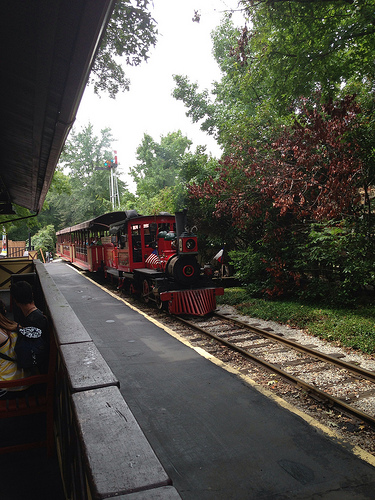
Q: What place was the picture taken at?
A: It was taken at the pavement.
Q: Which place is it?
A: It is a pavement.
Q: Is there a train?
A: Yes, there is a train.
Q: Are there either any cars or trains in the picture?
A: Yes, there is a train.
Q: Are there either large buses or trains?
A: Yes, there is a large train.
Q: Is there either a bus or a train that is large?
A: Yes, the train is large.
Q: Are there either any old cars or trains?
A: Yes, there is an old train.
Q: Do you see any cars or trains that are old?
A: Yes, the train is old.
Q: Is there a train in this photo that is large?
A: Yes, there is a train that is large.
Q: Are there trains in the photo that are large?
A: Yes, there is a train that is large.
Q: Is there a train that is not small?
A: Yes, there is a large train.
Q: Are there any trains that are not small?
A: Yes, there is a large train.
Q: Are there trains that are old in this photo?
A: Yes, there is an old train.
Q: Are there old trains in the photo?
A: Yes, there is an old train.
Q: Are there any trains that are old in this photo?
A: Yes, there is an old train.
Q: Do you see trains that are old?
A: Yes, there is a train that is old.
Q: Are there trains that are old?
A: Yes, there is a train that is old.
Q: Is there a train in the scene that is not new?
A: Yes, there is a old train.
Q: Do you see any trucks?
A: No, there are no trucks.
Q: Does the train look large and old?
A: Yes, the train is large and old.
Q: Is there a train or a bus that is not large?
A: No, there is a train but it is large.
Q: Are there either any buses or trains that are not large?
A: No, there is a train but it is large.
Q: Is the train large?
A: Yes, the train is large.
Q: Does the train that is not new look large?
A: Yes, the train is large.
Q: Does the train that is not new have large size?
A: Yes, the train is large.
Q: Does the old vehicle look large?
A: Yes, the train is large.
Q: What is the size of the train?
A: The train is large.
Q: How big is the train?
A: The train is large.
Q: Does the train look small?
A: No, the train is large.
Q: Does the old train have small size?
A: No, the train is large.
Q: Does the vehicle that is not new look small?
A: No, the train is large.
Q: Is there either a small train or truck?
A: No, there is a train but it is large.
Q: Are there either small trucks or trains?
A: No, there is a train but it is large.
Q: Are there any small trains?
A: No, there is a train but it is large.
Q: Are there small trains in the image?
A: No, there is a train but it is large.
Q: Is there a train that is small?
A: No, there is a train but it is large.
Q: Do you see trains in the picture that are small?
A: No, there is a train but it is large.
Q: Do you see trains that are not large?
A: No, there is a train but it is large.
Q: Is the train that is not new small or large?
A: The train is large.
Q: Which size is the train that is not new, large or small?
A: The train is large.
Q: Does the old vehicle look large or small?
A: The train is large.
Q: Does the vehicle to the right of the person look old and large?
A: Yes, the train is old and large.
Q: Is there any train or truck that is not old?
A: No, there is a train but it is old.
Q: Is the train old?
A: Yes, the train is old.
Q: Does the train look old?
A: Yes, the train is old.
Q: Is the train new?
A: No, the train is old.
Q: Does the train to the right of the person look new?
A: No, the train is old.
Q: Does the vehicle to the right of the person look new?
A: No, the train is old.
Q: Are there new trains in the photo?
A: No, there is a train but it is old.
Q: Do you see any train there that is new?
A: No, there is a train but it is old.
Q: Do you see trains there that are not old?
A: No, there is a train but it is old.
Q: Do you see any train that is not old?
A: No, there is a train but it is old.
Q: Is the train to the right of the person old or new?
A: The train is old.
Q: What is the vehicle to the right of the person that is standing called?
A: The vehicle is a train.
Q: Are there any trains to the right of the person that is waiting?
A: Yes, there is a train to the right of the person.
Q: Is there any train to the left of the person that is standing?
A: No, the train is to the right of the person.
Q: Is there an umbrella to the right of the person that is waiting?
A: No, there is a train to the right of the person.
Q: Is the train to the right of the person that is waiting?
A: Yes, the train is to the right of the person.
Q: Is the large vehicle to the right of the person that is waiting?
A: Yes, the train is to the right of the person.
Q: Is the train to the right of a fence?
A: No, the train is to the right of the person.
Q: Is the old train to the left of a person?
A: No, the train is to the right of a person.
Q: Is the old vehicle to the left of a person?
A: No, the train is to the right of a person.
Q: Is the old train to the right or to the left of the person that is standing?
A: The train is to the right of the person.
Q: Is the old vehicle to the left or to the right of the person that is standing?
A: The train is to the right of the person.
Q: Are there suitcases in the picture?
A: No, there are no suitcases.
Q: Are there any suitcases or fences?
A: No, there are no suitcases or fences.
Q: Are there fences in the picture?
A: No, there are no fences.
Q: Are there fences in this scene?
A: No, there are no fences.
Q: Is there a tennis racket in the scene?
A: No, there are no rackets.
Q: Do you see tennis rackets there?
A: No, there are no tennis rackets.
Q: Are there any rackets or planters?
A: No, there are no rackets or planters.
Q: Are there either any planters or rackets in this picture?
A: No, there are no rackets or planters.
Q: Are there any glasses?
A: No, there are no glasses.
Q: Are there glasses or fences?
A: No, there are no glasses or fences.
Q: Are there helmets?
A: No, there are no helmets.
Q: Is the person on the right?
A: No, the person is on the left of the image.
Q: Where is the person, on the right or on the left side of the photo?
A: The person is on the left of the image.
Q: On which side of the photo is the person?
A: The person is on the left of the image.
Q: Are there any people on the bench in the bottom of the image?
A: Yes, there is a person on the bench.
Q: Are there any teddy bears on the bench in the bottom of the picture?
A: No, there is a person on the bench.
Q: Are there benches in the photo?
A: Yes, there is a bench.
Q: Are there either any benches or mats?
A: Yes, there is a bench.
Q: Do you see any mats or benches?
A: Yes, there is a bench.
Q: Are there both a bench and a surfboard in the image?
A: No, there is a bench but no surfboards.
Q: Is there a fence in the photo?
A: No, there are no fences.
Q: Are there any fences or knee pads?
A: No, there are no fences or knee pads.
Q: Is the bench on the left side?
A: Yes, the bench is on the left of the image.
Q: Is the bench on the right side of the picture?
A: No, the bench is on the left of the image.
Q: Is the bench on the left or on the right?
A: The bench is on the left of the image.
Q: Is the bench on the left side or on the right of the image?
A: The bench is on the left of the image.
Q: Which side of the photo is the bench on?
A: The bench is on the left of the image.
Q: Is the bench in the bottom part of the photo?
A: Yes, the bench is in the bottom of the image.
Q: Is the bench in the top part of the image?
A: No, the bench is in the bottom of the image.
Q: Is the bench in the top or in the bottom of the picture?
A: The bench is in the bottom of the image.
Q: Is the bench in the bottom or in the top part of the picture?
A: The bench is in the bottom of the image.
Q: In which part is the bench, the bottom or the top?
A: The bench is in the bottom of the image.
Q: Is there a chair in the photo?
A: No, there are no chairs.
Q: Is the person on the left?
A: Yes, the person is on the left of the image.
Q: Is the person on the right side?
A: No, the person is on the left of the image.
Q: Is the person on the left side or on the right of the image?
A: The person is on the left of the image.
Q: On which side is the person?
A: The person is on the left of the image.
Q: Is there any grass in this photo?
A: Yes, there is grass.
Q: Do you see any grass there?
A: Yes, there is grass.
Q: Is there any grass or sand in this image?
A: Yes, there is grass.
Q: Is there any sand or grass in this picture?
A: Yes, there is grass.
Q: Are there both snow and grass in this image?
A: No, there is grass but no snow.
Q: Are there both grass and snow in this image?
A: No, there is grass but no snow.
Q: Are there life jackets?
A: No, there are no life jackets.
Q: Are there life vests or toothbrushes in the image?
A: No, there are no life vests or toothbrushes.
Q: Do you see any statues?
A: No, there are no statues.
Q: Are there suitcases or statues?
A: No, there are no statues or suitcases.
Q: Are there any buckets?
A: No, there are no buckets.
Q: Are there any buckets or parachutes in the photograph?
A: No, there are no buckets or parachutes.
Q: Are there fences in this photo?
A: No, there are no fences.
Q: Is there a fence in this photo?
A: No, there are no fences.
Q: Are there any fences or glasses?
A: No, there are no fences or glasses.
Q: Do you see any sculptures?
A: No, there are no sculptures.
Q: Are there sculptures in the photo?
A: No, there are no sculptures.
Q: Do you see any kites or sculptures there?
A: No, there are no sculptures or kites.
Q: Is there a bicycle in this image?
A: No, there are no bicycles.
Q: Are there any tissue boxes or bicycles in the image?
A: No, there are no bicycles or tissue boxes.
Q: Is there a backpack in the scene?
A: Yes, there is a backpack.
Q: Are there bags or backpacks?
A: Yes, there is a backpack.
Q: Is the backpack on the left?
A: Yes, the backpack is on the left of the image.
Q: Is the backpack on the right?
A: No, the backpack is on the left of the image.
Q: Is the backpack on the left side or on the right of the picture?
A: The backpack is on the left of the image.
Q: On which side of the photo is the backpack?
A: The backpack is on the left of the image.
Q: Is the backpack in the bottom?
A: Yes, the backpack is in the bottom of the image.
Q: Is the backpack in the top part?
A: No, the backpack is in the bottom of the image.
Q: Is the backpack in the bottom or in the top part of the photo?
A: The backpack is in the bottom of the image.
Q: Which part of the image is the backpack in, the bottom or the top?
A: The backpack is in the bottom of the image.